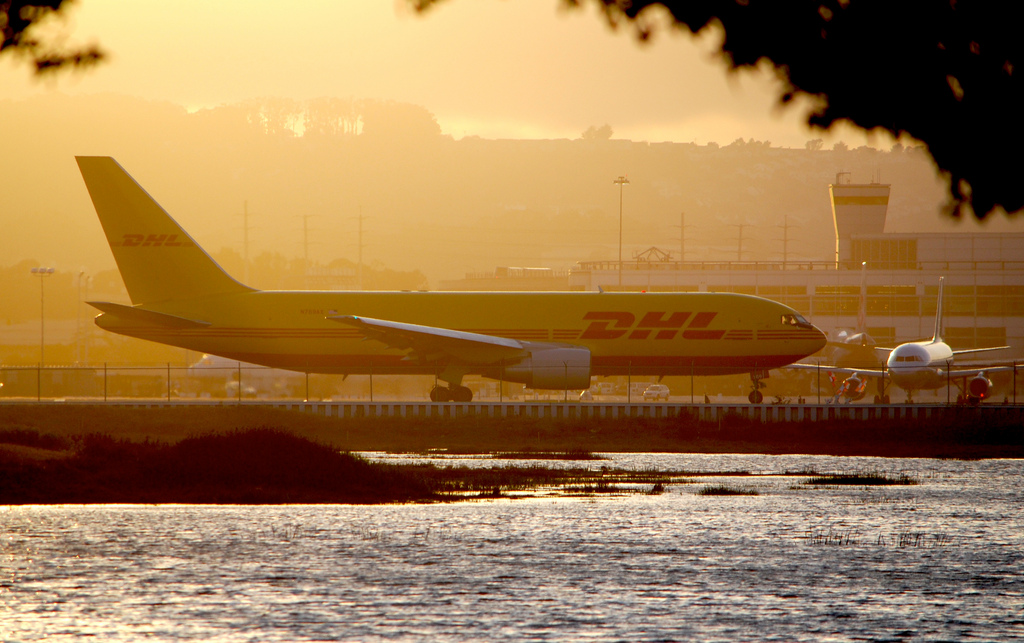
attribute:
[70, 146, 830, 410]
plane — large, yellow, red, commercial, dhl, parked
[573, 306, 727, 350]
sign — dhl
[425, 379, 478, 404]
wheels — down, rear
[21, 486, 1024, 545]
sunlight — reflected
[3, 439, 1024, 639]
water — bright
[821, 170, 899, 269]
tower — control, flight control, airport, traffic control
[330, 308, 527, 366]
wing — white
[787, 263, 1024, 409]
plane — white, preparing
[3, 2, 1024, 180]
sky — hazy, smoke, smog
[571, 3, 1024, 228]
tree — edge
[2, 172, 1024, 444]
airport — scene, background, terminal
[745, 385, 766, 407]
wheels — down